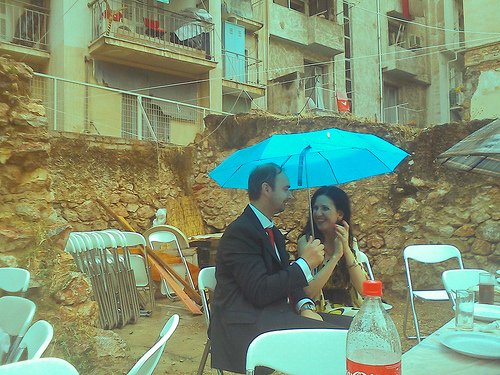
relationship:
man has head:
[208, 161, 355, 362] [246, 161, 297, 214]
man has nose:
[208, 161, 355, 362] [286, 189, 293, 200]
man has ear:
[208, 161, 355, 362] [260, 180, 270, 196]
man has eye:
[208, 161, 355, 362] [283, 185, 289, 191]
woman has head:
[295, 182, 367, 316] [312, 183, 349, 232]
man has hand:
[208, 161, 355, 362] [300, 231, 324, 269]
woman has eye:
[295, 182, 367, 316] [321, 205, 329, 212]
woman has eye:
[295, 182, 367, 316] [313, 206, 319, 212]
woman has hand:
[295, 182, 367, 316] [333, 217, 350, 252]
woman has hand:
[295, 182, 367, 316] [333, 234, 345, 258]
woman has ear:
[295, 182, 367, 316] [334, 208, 345, 221]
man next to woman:
[208, 161, 355, 362] [295, 182, 367, 316]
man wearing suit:
[208, 161, 355, 362] [210, 201, 355, 374]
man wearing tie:
[208, 161, 355, 362] [265, 222, 275, 248]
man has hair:
[208, 161, 355, 362] [247, 161, 283, 204]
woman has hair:
[295, 182, 367, 316] [300, 184, 351, 285]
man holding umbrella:
[208, 161, 355, 362] [208, 128, 410, 274]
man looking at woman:
[208, 161, 355, 362] [295, 182, 367, 316]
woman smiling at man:
[295, 182, 367, 316] [208, 161, 355, 362]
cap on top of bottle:
[359, 277, 385, 297] [343, 275, 403, 374]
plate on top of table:
[436, 329, 499, 361] [397, 298, 499, 373]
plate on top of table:
[453, 301, 498, 321] [397, 298, 499, 373]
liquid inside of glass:
[477, 281, 494, 305] [477, 268, 496, 304]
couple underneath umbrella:
[208, 161, 369, 373] [208, 128, 410, 274]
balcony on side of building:
[87, 0, 217, 78] [0, 0, 463, 148]